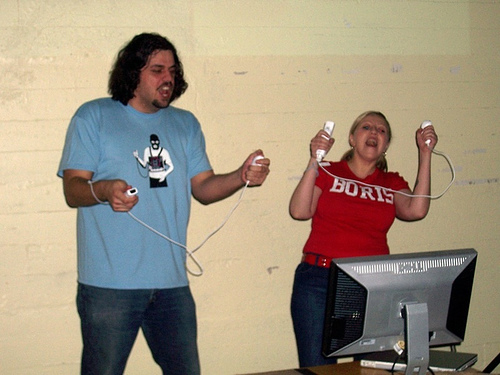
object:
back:
[359, 272, 455, 343]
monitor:
[319, 244, 482, 365]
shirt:
[299, 160, 410, 264]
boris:
[328, 174, 395, 206]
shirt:
[57, 95, 214, 290]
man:
[55, 34, 271, 375]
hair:
[105, 32, 188, 109]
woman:
[285, 110, 439, 372]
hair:
[342, 110, 394, 172]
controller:
[125, 186, 141, 197]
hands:
[100, 178, 140, 214]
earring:
[380, 150, 389, 156]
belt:
[295, 251, 332, 269]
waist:
[299, 241, 393, 275]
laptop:
[359, 349, 481, 373]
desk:
[234, 360, 489, 374]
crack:
[453, 178, 500, 187]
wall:
[0, 0, 499, 374]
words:
[394, 259, 424, 273]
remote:
[313, 121, 338, 161]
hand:
[305, 131, 335, 160]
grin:
[363, 136, 385, 152]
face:
[352, 115, 390, 161]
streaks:
[378, 157, 387, 174]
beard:
[150, 99, 177, 110]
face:
[136, 52, 181, 111]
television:
[316, 246, 480, 366]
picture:
[132, 132, 177, 188]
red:
[346, 225, 371, 252]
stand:
[399, 298, 432, 374]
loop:
[311, 251, 322, 264]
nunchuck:
[245, 154, 266, 171]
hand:
[237, 148, 274, 189]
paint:
[414, 80, 432, 101]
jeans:
[72, 281, 204, 374]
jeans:
[286, 252, 336, 367]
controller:
[312, 121, 336, 164]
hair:
[150, 80, 178, 114]